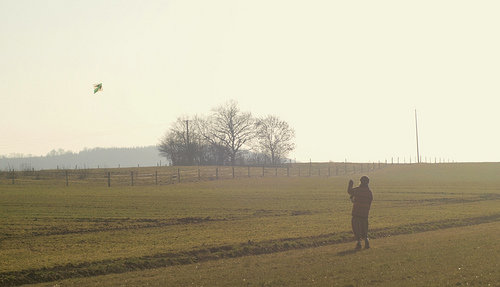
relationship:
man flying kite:
[333, 161, 390, 258] [81, 73, 119, 111]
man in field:
[333, 161, 390, 258] [3, 163, 498, 283]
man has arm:
[333, 161, 390, 258] [341, 171, 360, 211]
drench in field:
[27, 203, 499, 280] [3, 163, 498, 283]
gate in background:
[29, 159, 477, 171] [18, 116, 474, 204]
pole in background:
[401, 96, 428, 172] [18, 116, 474, 204]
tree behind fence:
[140, 98, 304, 168] [15, 149, 480, 173]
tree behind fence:
[154, 100, 299, 168] [15, 149, 480, 173]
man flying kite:
[345, 175, 372, 249] [81, 73, 119, 111]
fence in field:
[15, 149, 480, 173] [3, 163, 498, 283]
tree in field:
[154, 100, 299, 168] [3, 163, 498, 283]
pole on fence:
[401, 96, 428, 172] [15, 149, 480, 173]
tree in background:
[154, 100, 299, 168] [18, 116, 474, 204]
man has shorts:
[345, 175, 372, 249] [345, 214, 376, 240]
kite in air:
[81, 73, 119, 111] [42, 41, 430, 173]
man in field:
[345, 175, 372, 249] [3, 163, 498, 283]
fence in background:
[15, 149, 480, 173] [18, 116, 474, 204]